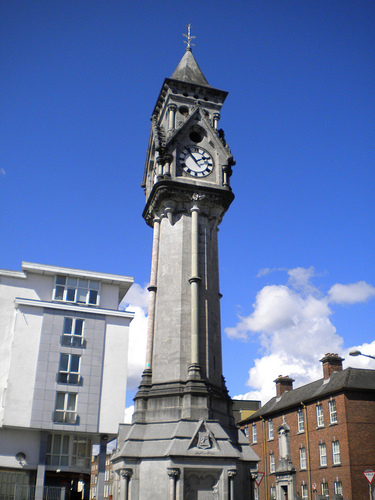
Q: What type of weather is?
A: It is cloudy.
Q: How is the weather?
A: It is cloudy.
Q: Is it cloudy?
A: Yes, it is cloudy.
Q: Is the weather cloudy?
A: Yes, it is cloudy.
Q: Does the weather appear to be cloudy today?
A: Yes, it is cloudy.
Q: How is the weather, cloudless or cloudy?
A: It is cloudy.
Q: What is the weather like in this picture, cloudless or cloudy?
A: It is cloudy.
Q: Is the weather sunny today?
A: No, it is cloudy.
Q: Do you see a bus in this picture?
A: No, there are no buses.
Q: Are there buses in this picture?
A: No, there are no buses.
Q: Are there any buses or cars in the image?
A: No, there are no buses or cars.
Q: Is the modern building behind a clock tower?
A: Yes, the building is behind a clock tower.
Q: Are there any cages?
A: No, there are no cages.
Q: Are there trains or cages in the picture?
A: No, there are no cages or trains.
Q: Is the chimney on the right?
A: Yes, the chimney is on the right of the image.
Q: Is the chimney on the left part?
A: No, the chimney is on the right of the image.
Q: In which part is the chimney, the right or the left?
A: The chimney is on the right of the image.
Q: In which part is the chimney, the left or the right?
A: The chimney is on the right of the image.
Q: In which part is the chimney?
A: The chimney is on the right of the image.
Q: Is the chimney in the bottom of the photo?
A: Yes, the chimney is in the bottom of the image.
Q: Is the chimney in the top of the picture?
A: No, the chimney is in the bottom of the image.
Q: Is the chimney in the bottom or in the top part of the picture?
A: The chimney is in the bottom of the image.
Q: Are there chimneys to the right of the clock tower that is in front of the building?
A: Yes, there is a chimney to the right of the clock tower.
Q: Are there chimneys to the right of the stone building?
A: Yes, there is a chimney to the right of the clock tower.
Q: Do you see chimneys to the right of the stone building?
A: Yes, there is a chimney to the right of the clock tower.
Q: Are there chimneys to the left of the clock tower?
A: No, the chimney is to the right of the clock tower.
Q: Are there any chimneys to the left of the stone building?
A: No, the chimney is to the right of the clock tower.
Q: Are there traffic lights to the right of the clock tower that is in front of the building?
A: No, there is a chimney to the right of the clock tower.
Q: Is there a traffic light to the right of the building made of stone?
A: No, there is a chimney to the right of the clock tower.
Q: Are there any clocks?
A: Yes, there is a clock.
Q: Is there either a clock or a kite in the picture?
A: Yes, there is a clock.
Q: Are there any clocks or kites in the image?
A: Yes, there is a clock.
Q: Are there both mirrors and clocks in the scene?
A: No, there is a clock but no mirrors.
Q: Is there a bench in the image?
A: No, there are no benches.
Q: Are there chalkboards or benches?
A: No, there are no benches or chalkboards.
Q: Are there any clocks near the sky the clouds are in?
A: Yes, there is a clock near the sky.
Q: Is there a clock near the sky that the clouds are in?
A: Yes, there is a clock near the sky.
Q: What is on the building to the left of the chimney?
A: The clock is on the clock tower.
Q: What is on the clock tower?
A: The clock is on the clock tower.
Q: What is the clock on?
A: The clock is on the clock tower.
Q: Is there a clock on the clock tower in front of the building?
A: Yes, there is a clock on the clock tower.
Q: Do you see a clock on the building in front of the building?
A: Yes, there is a clock on the clock tower.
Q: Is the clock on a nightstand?
A: No, the clock is on a clock tower.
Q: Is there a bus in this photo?
A: No, there are no buses.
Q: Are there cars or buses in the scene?
A: No, there are no buses or cars.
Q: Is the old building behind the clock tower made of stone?
A: Yes, the building is behind the clock tower.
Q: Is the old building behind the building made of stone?
A: Yes, the building is behind the clock tower.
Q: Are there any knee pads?
A: No, there are no knee pads.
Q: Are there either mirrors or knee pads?
A: No, there are no knee pads or mirrors.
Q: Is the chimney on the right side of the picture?
A: Yes, the chimney is on the right of the image.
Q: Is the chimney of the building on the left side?
A: No, the chimney is on the right of the image.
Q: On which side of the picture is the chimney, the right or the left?
A: The chimney is on the right of the image.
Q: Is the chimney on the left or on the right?
A: The chimney is on the right of the image.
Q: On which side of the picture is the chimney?
A: The chimney is on the right of the image.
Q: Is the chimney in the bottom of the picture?
A: Yes, the chimney is in the bottom of the image.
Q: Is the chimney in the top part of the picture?
A: No, the chimney is in the bottom of the image.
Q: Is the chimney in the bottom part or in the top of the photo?
A: The chimney is in the bottom of the image.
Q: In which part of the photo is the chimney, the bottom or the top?
A: The chimney is in the bottom of the image.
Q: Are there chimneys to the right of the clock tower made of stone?
A: Yes, there is a chimney to the right of the clock tower.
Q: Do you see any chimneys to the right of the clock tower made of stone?
A: Yes, there is a chimney to the right of the clock tower.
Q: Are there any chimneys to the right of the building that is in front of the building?
A: Yes, there is a chimney to the right of the clock tower.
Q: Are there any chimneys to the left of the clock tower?
A: No, the chimney is to the right of the clock tower.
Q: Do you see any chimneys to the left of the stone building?
A: No, the chimney is to the right of the clock tower.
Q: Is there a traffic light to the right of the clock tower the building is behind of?
A: No, there is a chimney to the right of the clock tower.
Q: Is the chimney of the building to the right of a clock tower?
A: Yes, the chimney is to the right of a clock tower.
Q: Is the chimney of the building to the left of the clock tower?
A: No, the chimney is to the right of the clock tower.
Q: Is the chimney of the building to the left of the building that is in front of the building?
A: No, the chimney is to the right of the clock tower.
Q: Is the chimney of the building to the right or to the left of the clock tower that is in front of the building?
A: The chimney is to the right of the clock tower.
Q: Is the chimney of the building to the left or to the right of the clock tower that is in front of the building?
A: The chimney is to the right of the clock tower.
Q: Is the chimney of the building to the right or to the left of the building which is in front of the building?
A: The chimney is to the right of the clock tower.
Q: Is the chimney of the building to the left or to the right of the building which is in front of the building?
A: The chimney is to the right of the clock tower.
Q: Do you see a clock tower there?
A: Yes, there is a clock tower.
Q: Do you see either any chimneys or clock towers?
A: Yes, there is a clock tower.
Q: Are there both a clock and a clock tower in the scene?
A: Yes, there are both a clock tower and a clock.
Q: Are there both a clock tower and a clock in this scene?
A: Yes, there are both a clock tower and a clock.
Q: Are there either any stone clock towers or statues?
A: Yes, there is a stone clock tower.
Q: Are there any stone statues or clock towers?
A: Yes, there is a stone clock tower.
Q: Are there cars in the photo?
A: No, there are no cars.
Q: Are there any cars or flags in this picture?
A: No, there are no cars or flags.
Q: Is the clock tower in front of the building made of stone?
A: Yes, the clock tower is made of stone.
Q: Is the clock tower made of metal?
A: No, the clock tower is made of stone.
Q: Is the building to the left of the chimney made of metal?
A: No, the clock tower is made of stone.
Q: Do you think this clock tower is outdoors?
A: Yes, the clock tower is outdoors.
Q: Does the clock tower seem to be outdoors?
A: Yes, the clock tower is outdoors.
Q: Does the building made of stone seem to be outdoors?
A: Yes, the clock tower is outdoors.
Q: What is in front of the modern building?
A: The clock tower is in front of the building.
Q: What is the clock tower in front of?
A: The clock tower is in front of the building.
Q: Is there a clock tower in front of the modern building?
A: Yes, there is a clock tower in front of the building.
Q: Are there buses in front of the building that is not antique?
A: No, there is a clock tower in front of the building.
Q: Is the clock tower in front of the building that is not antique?
A: Yes, the clock tower is in front of the building.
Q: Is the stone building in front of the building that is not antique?
A: Yes, the clock tower is in front of the building.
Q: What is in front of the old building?
A: The clock tower is in front of the building.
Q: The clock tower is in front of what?
A: The clock tower is in front of the building.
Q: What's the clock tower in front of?
A: The clock tower is in front of the building.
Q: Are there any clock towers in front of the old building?
A: Yes, there is a clock tower in front of the building.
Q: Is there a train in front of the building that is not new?
A: No, there is a clock tower in front of the building.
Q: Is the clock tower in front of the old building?
A: Yes, the clock tower is in front of the building.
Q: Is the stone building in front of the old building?
A: Yes, the clock tower is in front of the building.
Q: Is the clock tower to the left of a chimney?
A: Yes, the clock tower is to the left of a chimney.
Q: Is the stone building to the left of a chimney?
A: Yes, the clock tower is to the left of a chimney.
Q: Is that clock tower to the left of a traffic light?
A: No, the clock tower is to the left of a chimney.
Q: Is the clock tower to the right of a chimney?
A: No, the clock tower is to the left of a chimney.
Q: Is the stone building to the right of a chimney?
A: No, the clock tower is to the left of a chimney.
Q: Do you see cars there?
A: No, there are no cars.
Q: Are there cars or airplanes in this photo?
A: No, there are no cars or airplanes.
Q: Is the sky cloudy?
A: Yes, the sky is cloudy.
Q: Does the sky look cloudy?
A: Yes, the sky is cloudy.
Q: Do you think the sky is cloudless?
A: No, the sky is cloudy.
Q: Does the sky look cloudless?
A: No, the sky is cloudy.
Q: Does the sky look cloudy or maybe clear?
A: The sky is cloudy.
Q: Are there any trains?
A: No, there are no trains.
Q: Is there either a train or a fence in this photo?
A: No, there are no trains or fences.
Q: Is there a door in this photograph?
A: Yes, there is a door.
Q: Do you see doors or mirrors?
A: Yes, there is a door.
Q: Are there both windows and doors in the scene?
A: Yes, there are both a door and windows.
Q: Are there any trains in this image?
A: No, there are no trains.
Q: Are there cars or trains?
A: No, there are no trains or cars.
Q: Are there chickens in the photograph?
A: No, there are no chickens.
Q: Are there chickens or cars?
A: No, there are no chickens or cars.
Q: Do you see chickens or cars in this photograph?
A: No, there are no chickens or cars.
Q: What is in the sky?
A: The clouds are in the sky.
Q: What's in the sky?
A: The clouds are in the sky.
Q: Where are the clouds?
A: The clouds are in the sky.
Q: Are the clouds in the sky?
A: Yes, the clouds are in the sky.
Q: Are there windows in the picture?
A: Yes, there is a window.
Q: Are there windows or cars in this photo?
A: Yes, there is a window.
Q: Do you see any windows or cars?
A: Yes, there is a window.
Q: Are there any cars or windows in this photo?
A: Yes, there is a window.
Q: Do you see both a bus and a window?
A: No, there is a window but no buses.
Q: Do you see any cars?
A: No, there are no cars.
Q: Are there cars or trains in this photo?
A: No, there are no cars or trains.